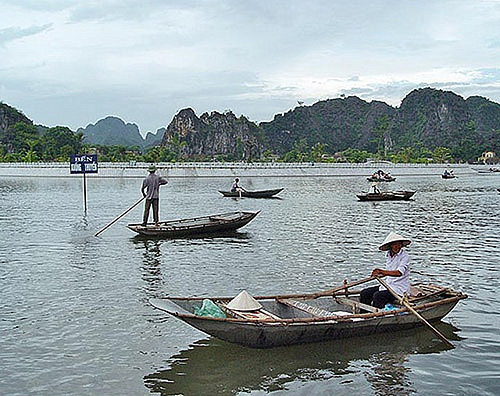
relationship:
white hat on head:
[375, 229, 412, 251] [375, 237, 405, 253]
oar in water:
[373, 275, 455, 345] [1, 160, 497, 393]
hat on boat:
[229, 289, 261, 313] [147, 284, 470, 346]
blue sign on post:
[69, 150, 100, 180] [78, 174, 91, 227]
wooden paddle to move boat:
[378, 289, 477, 349] [136, 251, 493, 364]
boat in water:
[147, 284, 470, 346] [1, 160, 497, 393]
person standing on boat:
[151, 164, 164, 201] [127, 210, 261, 240]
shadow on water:
[149, 340, 462, 393] [19, 258, 161, 367]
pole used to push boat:
[82, 182, 149, 252] [118, 206, 265, 245]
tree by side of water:
[341, 144, 367, 165] [294, 197, 482, 241]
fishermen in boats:
[80, 147, 491, 363] [148, 281, 468, 348]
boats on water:
[148, 281, 468, 348] [40, 233, 305, 292]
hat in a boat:
[228, 291, 261, 311] [147, 278, 470, 350]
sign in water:
[57, 152, 107, 223] [1, 160, 497, 393]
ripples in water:
[380, 203, 495, 244] [1, 160, 497, 393]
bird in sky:
[294, 98, 306, 108] [234, 12, 402, 97]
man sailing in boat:
[359, 209, 436, 323] [147, 274, 482, 343]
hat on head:
[379, 229, 413, 245] [386, 238, 404, 256]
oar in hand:
[88, 189, 173, 246] [369, 267, 382, 281]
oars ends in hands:
[354, 277, 394, 295] [368, 265, 385, 276]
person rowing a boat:
[231, 176, 241, 192] [218, 187, 284, 199]